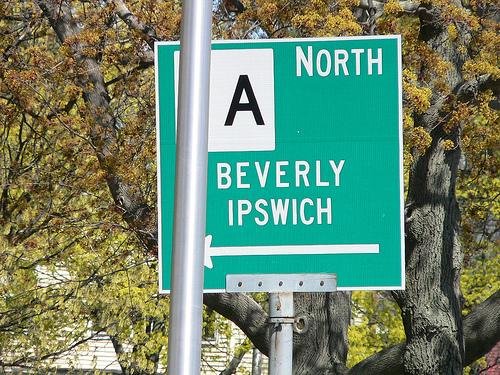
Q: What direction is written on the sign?
A: North.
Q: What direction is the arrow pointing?
A: Left.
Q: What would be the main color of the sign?
A: Green and white.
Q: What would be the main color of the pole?
A: Silver.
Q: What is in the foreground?
A: Pole.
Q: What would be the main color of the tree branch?
A: Brown.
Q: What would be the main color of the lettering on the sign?
A: White.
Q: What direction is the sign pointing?
A: LEft.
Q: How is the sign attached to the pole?
A: Bolts.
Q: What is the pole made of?
A: Steel.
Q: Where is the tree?
A: Behind the sign.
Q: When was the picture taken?
A: During day hours.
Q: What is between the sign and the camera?
A: A metal pole.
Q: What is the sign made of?
A: Metal.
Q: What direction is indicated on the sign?
A: North.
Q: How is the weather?
A: Clear.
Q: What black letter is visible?
A: A.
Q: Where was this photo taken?
A: By a large tree and sign.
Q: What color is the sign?
A: Green.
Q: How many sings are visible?
A: One.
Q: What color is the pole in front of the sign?
A: Silver.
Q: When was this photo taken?
A: Outside, during the daytime.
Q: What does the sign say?
A: A North Beverly IPSWICH.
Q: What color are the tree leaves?
A: Orange and green.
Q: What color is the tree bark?
A: Gray.